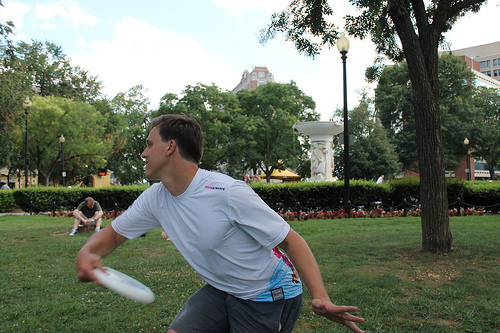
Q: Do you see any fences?
A: No, there are no fences.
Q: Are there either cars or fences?
A: No, there are no fences or cars.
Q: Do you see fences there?
A: No, there are no fences.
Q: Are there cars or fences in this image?
A: No, there are no fences or cars.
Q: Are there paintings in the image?
A: No, there are no paintings.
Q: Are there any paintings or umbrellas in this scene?
A: No, there are no paintings or umbrellas.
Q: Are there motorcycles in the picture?
A: No, there are no motorcycles.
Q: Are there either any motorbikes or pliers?
A: No, there are no motorbikes or pliers.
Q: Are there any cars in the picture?
A: No, there are no cars.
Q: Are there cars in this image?
A: No, there are no cars.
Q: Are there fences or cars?
A: No, there are no cars or fences.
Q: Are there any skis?
A: No, there are no skis.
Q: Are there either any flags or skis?
A: No, there are no skis or flags.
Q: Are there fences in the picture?
A: No, there are no fences.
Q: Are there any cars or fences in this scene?
A: No, there are no fences or cars.